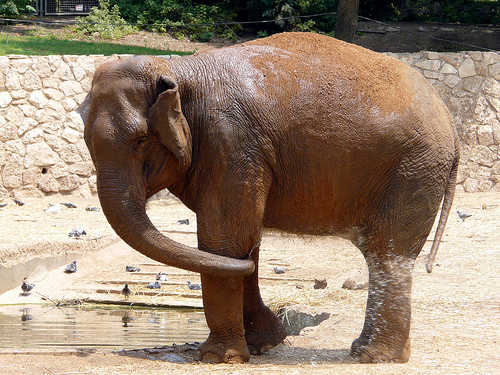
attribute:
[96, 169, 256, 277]
trunk — long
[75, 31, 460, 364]
elephant — brown, giant, standing, animal, gray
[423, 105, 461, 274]
tail — long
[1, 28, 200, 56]
grass — green, pretty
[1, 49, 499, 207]
wall — tan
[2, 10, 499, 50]
rope — thin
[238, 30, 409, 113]
dirt — brown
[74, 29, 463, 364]
animal — huge